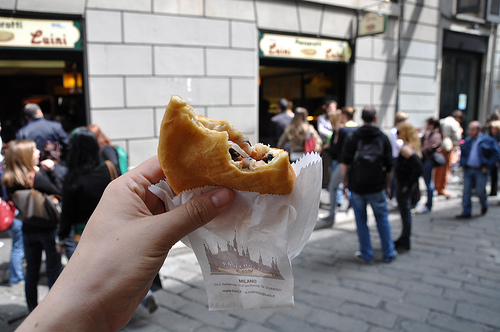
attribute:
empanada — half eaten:
[154, 94, 299, 222]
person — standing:
[12, 160, 237, 330]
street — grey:
[131, 204, 500, 332]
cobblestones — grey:
[132, 206, 499, 332]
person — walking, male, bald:
[459, 123, 495, 220]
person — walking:
[326, 106, 361, 226]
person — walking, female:
[61, 130, 121, 262]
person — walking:
[419, 120, 445, 212]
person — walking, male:
[434, 109, 463, 205]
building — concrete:
[2, 1, 500, 188]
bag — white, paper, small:
[149, 152, 324, 310]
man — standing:
[339, 105, 400, 262]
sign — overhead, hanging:
[357, 2, 389, 38]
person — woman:
[278, 107, 322, 160]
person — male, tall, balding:
[15, 102, 66, 147]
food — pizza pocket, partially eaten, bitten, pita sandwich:
[156, 94, 301, 211]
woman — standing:
[393, 123, 425, 255]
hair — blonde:
[397, 121, 425, 158]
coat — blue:
[459, 136, 499, 169]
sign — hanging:
[259, 32, 354, 65]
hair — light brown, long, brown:
[4, 139, 40, 192]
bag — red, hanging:
[303, 133, 316, 154]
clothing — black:
[396, 153, 424, 240]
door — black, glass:
[443, 34, 491, 130]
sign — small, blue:
[458, 94, 468, 111]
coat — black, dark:
[10, 117, 70, 160]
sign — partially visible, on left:
[0, 20, 85, 53]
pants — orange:
[435, 145, 452, 195]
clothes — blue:
[458, 136, 498, 215]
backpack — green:
[114, 148, 130, 175]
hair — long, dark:
[64, 129, 102, 197]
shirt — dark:
[56, 162, 121, 236]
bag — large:
[13, 170, 63, 223]